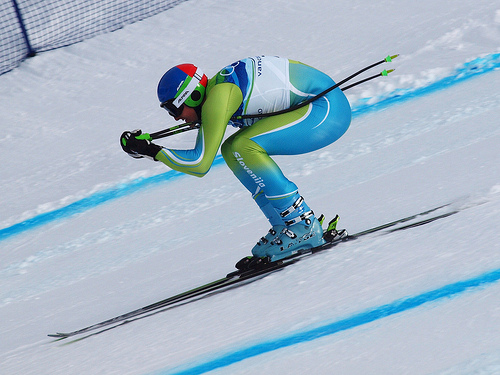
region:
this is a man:
[127, 29, 359, 301]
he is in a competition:
[127, 27, 369, 267]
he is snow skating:
[134, 24, 376, 266]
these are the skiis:
[211, 238, 280, 298]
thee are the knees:
[225, 122, 276, 185]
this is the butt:
[307, 90, 353, 135]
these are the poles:
[362, 49, 403, 88]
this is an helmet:
[161, 66, 205, 102]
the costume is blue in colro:
[307, 97, 349, 137]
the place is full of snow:
[136, 212, 190, 259]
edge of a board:
[192, 283, 243, 340]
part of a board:
[380, 209, 404, 230]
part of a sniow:
[388, 184, 422, 212]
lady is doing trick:
[136, 49, 397, 342]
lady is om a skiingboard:
[123, 49, 368, 284]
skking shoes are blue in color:
[250, 210, 331, 255]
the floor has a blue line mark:
[330, 282, 450, 359]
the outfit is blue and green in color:
[193, 54, 326, 226]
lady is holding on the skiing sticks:
[115, 64, 373, 176]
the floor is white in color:
[27, 86, 93, 128]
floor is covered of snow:
[33, 75, 94, 120]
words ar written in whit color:
[234, 150, 276, 198]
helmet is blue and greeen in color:
[159, 58, 208, 109]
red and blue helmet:
[145, 65, 200, 131]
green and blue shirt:
[155, 56, 286, 131]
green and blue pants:
[247, 90, 337, 193]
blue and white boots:
[226, 193, 321, 239]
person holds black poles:
[133, 60, 404, 150]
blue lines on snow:
[237, 283, 488, 370]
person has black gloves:
[106, 121, 164, 163]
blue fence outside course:
[0, 10, 175, 87]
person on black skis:
[72, 185, 485, 373]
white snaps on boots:
[263, 195, 322, 255]